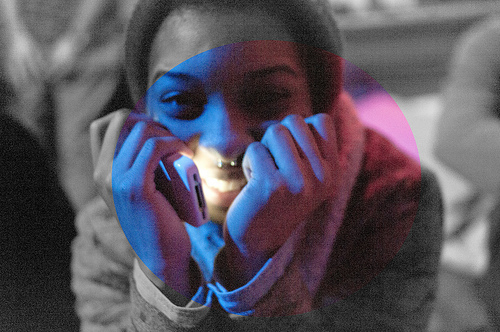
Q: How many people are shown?
A: One.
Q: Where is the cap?
A: Girl's head.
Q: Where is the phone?
A: Girl's hands.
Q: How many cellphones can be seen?
A: One.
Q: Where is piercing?
A: Girl's nose.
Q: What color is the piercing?
A: Silver.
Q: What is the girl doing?
A: Smiling.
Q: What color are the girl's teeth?
A: White.